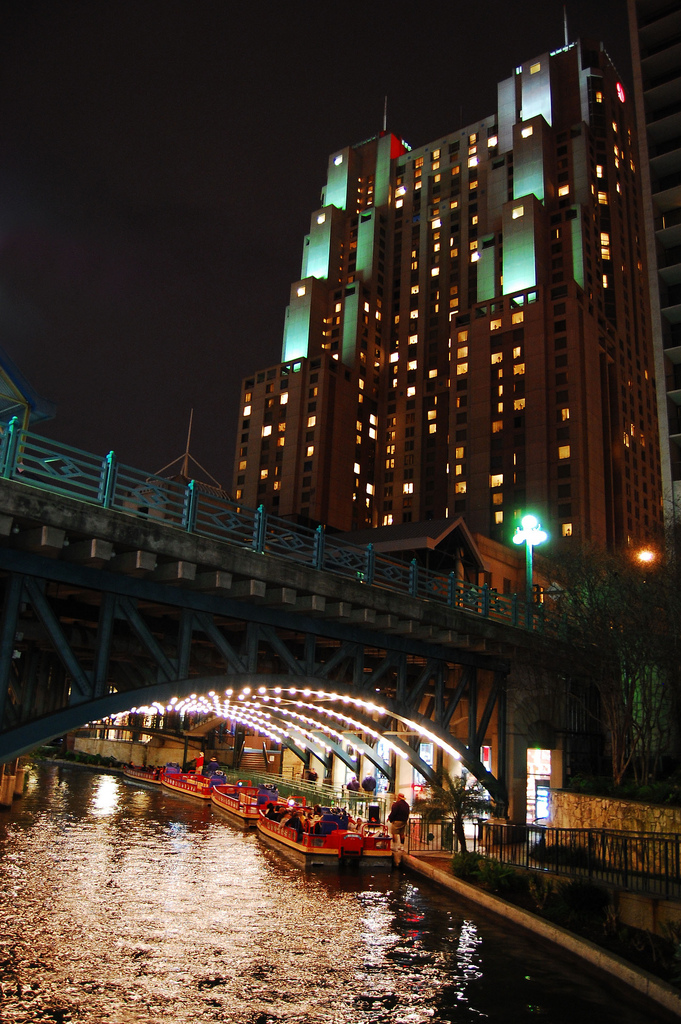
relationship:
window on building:
[455, 329, 468, 342] [231, 31, 672, 594]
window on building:
[513, 398, 527, 413] [236, 40, 678, 640]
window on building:
[485, 315, 502, 334] [231, 31, 672, 594]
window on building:
[508, 307, 530, 328] [231, 31, 672, 594]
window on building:
[508, 340, 522, 356] [231, 31, 672, 594]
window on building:
[484, 348, 504, 365] [231, 31, 672, 594]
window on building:
[512, 358, 527, 374] [231, 31, 672, 594]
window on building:
[452, 345, 471, 359] [231, 31, 672, 594]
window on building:
[513, 399, 525, 413] [231, 31, 672, 594]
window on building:
[490, 348, 504, 365] [366, 188, 545, 424]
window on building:
[551, 332, 574, 352] [340, 190, 508, 412]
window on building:
[442, 252, 498, 296] [330, 185, 610, 467]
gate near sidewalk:
[403, 812, 679, 900] [418, 842, 679, 995]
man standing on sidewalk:
[386, 792, 411, 853] [403, 847, 679, 1015]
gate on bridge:
[1, 414, 572, 634] [1, 411, 619, 841]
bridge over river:
[1, 411, 619, 841] [2, 752, 677, 1020]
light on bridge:
[509, 511, 549, 606] [1, 411, 619, 841]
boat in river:
[208, 777, 274, 821] [2, 752, 677, 1020]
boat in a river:
[255, 783, 399, 895] [2, 752, 677, 1020]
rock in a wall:
[643, 807, 663, 826] [541, 785, 680, 887]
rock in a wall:
[651, 806, 664, 819] [541, 785, 680, 887]